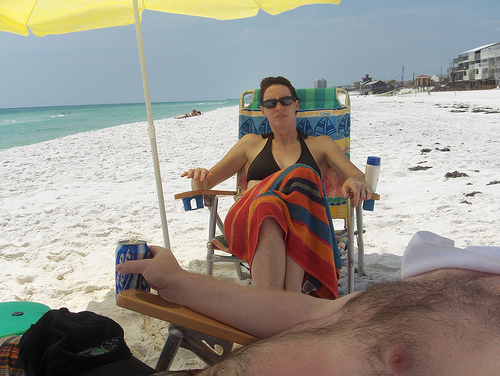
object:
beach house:
[432, 42, 500, 91]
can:
[110, 239, 149, 307]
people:
[173, 107, 205, 122]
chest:
[256, 258, 496, 375]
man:
[0, 243, 498, 373]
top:
[243, 128, 322, 182]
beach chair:
[175, 83, 383, 294]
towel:
[221, 169, 340, 299]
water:
[0, 96, 87, 126]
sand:
[2, 81, 497, 372]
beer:
[117, 239, 154, 304]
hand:
[117, 234, 195, 307]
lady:
[181, 76, 372, 293]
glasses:
[261, 93, 299, 110]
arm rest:
[191, 273, 265, 337]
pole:
[132, 1, 172, 271]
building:
[412, 76, 434, 90]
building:
[352, 70, 402, 95]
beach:
[0, 79, 491, 374]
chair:
[113, 280, 303, 376]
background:
[0, 0, 500, 110]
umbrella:
[0, 0, 337, 260]